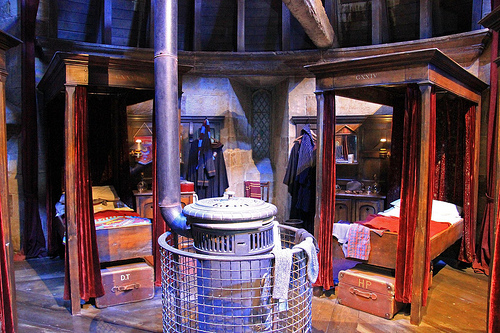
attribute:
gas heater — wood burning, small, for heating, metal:
[184, 189, 281, 330]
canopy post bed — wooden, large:
[58, 46, 179, 301]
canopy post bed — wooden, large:
[315, 58, 485, 321]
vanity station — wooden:
[325, 121, 381, 242]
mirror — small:
[331, 126, 353, 163]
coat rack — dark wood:
[284, 122, 318, 216]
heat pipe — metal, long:
[148, 4, 187, 234]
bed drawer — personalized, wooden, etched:
[87, 260, 153, 305]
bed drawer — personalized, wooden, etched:
[331, 260, 397, 320]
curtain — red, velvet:
[70, 82, 162, 293]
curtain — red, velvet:
[321, 85, 479, 315]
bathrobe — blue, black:
[294, 126, 321, 206]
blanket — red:
[82, 203, 136, 222]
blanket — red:
[361, 212, 455, 244]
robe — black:
[192, 134, 223, 199]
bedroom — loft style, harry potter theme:
[3, 2, 499, 325]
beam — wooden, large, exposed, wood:
[282, 1, 337, 46]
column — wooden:
[66, 64, 99, 310]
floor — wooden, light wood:
[17, 243, 499, 332]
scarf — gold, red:
[244, 181, 265, 199]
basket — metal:
[156, 231, 319, 332]